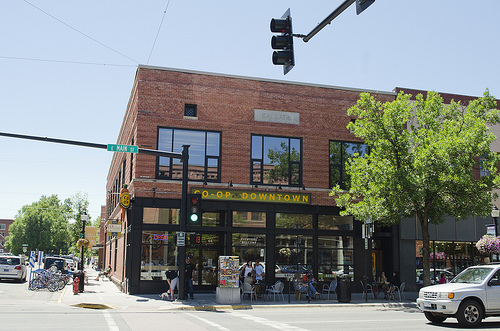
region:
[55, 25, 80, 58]
white clouds in blue sky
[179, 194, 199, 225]
green light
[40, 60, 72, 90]
white clouds in blue sky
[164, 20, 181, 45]
white clouds in blue sky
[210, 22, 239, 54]
white clouds in blue sky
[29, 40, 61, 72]
white clouds in blue sky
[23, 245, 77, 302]
Row of bicycles parked.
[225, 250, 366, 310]
Outside table and chair dining area.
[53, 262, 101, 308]
Red fire hydrant on corner.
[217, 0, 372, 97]
Traffic lights on black metal pole.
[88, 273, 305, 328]
White lines painted on road for crosswalk.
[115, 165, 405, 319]
Large brick building with green and yellow sign.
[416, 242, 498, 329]
White vehicle coming to intersection.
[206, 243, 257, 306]
White outside display with items on it.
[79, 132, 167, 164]
Green and white street sign on traffic pole.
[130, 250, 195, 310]
Man walking small white dog.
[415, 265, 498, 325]
A white suv.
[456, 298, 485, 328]
A front driver wheel of an suv.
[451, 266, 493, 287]
A clear windshield on an suv.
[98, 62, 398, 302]
A brick building that says CO-OP.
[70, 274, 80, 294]
A red fire hydrant.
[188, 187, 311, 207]
CO-OP DOWNTOWN sign on a building.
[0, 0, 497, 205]
A blue sky.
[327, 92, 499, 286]
A grey and green large tree by an suv.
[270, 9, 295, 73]
A black traffic light over the road.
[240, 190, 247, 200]
Yellow D in DOWNTOWN.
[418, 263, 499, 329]
a white truck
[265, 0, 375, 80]
a traffic light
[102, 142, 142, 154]
a green and white street sign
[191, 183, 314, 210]
the store banner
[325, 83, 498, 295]
a tree in front of the store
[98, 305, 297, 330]
the crosswalk in front of store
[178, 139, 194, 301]
the black pole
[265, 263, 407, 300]
chairs in front of the store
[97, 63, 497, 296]
a red brick building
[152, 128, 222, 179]
THIS IS A WINDOW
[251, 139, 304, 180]
THIS IS A WINDOW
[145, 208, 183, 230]
THIS IS A WINDOW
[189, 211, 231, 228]
THIS IS A WINDOW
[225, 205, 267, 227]
THIS IS A WINDOW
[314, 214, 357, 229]
THIS IS A WINDOW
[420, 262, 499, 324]
THIS IS A CAR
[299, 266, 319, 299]
THIS IS A PERSON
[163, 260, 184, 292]
THIS IS A PERSON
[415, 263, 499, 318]
A white truck on a road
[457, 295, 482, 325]
A front tire on a truck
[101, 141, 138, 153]
A green sign on a pole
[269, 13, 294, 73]
A traffic light on a pole